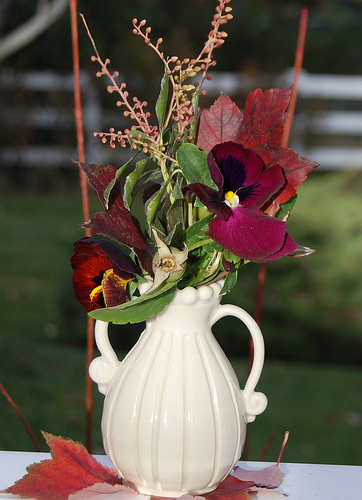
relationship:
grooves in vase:
[143, 329, 175, 384] [92, 240, 275, 494]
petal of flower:
[205, 206, 285, 259] [177, 136, 298, 263]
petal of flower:
[180, 179, 233, 220] [177, 136, 298, 263]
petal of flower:
[205, 139, 263, 202] [177, 136, 298, 263]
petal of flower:
[238, 161, 287, 210] [177, 136, 298, 263]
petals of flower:
[70, 235, 106, 299] [177, 136, 298, 263]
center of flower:
[222, 189, 239, 211] [192, 117, 332, 226]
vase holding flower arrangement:
[87, 273, 268, 497] [60, 0, 322, 326]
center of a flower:
[222, 189, 239, 211] [179, 142, 300, 271]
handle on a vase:
[211, 302, 270, 426] [87, 273, 268, 497]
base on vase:
[124, 468, 230, 499] [88, 264, 288, 498]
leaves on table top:
[0, 419, 316, 498] [0, 445, 361, 497]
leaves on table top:
[67, 68, 327, 344] [0, 445, 361, 497]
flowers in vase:
[64, 2, 316, 325] [87, 273, 268, 497]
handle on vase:
[211, 302, 270, 419] [87, 273, 268, 497]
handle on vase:
[87, 298, 156, 399] [87, 273, 268, 497]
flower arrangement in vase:
[60, 0, 322, 326] [87, 273, 268, 497]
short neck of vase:
[140, 300, 219, 332] [87, 273, 268, 497]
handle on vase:
[211, 302, 270, 426] [87, 273, 268, 497]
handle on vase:
[87, 298, 156, 392] [87, 273, 268, 497]